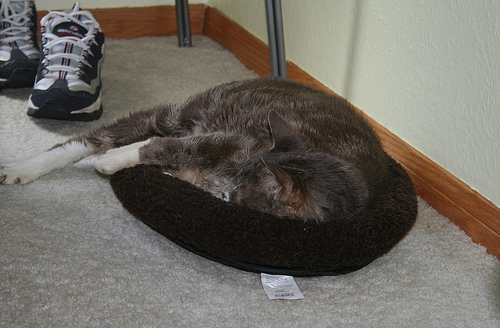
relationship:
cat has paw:
[1, 77, 392, 217] [8, 141, 89, 187]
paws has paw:
[0, 127, 166, 199] [74, 138, 147, 176]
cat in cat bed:
[1, 77, 392, 217] [117, 175, 430, 281]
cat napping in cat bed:
[1, 77, 392, 217] [110, 154, 433, 300]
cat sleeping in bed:
[1, 77, 392, 217] [123, 137, 437, 296]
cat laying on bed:
[1, 77, 392, 217] [144, 187, 424, 282]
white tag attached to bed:
[258, 271, 306, 301] [109, 153, 419, 277]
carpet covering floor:
[7, 34, 498, 318] [2, 33, 483, 325]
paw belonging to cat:
[0, 140, 94, 184] [1, 77, 392, 217]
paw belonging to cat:
[91, 134, 150, 174] [16, 72, 374, 240]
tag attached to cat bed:
[258, 270, 305, 301] [109, 137, 420, 278]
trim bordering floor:
[0, 2, 499, 261] [2, 33, 483, 325]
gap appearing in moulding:
[200, 2, 210, 34] [33, 2, 483, 252]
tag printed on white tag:
[258, 270, 305, 301] [260, 271, 306, 306]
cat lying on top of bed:
[1, 77, 392, 217] [99, 128, 434, 302]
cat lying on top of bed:
[1, 77, 392, 217] [132, 159, 422, 288]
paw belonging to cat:
[91, 134, 150, 174] [1, 77, 392, 217]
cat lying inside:
[1, 77, 392, 217] [2, 0, 484, 324]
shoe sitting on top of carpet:
[2, 1, 43, 89] [7, 34, 498, 318]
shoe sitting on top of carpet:
[25, 2, 105, 118] [7, 34, 498, 318]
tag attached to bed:
[258, 270, 305, 301] [109, 153, 419, 277]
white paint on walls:
[35, 0, 499, 216] [33, 0, 499, 211]